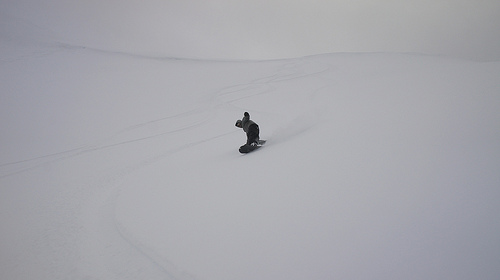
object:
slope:
[24, 11, 474, 101]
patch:
[224, 239, 282, 278]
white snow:
[0, 2, 497, 275]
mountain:
[5, 32, 487, 279]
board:
[238, 138, 269, 154]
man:
[235, 112, 260, 148]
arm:
[241, 115, 250, 120]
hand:
[242, 112, 250, 121]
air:
[0, 0, 498, 279]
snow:
[297, 57, 483, 263]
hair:
[236, 120, 242, 128]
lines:
[103, 128, 239, 279]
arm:
[212, 105, 281, 165]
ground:
[19, 62, 486, 274]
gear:
[238, 110, 259, 148]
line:
[61, 43, 500, 65]